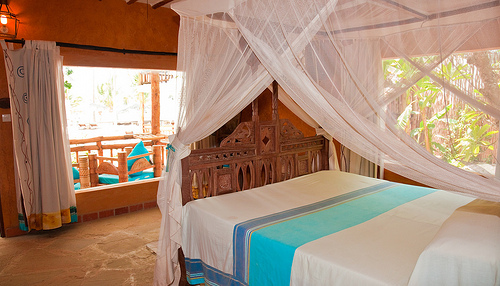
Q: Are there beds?
A: Yes, there is a bed.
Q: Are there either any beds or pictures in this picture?
A: Yes, there is a bed.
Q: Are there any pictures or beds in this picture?
A: Yes, there is a bed.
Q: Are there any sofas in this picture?
A: No, there are no sofas.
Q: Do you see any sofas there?
A: No, there are no sofas.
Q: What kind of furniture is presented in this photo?
A: The furniture is a bed.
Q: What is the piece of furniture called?
A: The piece of furniture is a bed.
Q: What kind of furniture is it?
A: The piece of furniture is a bed.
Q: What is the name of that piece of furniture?
A: This is a bed.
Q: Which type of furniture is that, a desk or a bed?
A: This is a bed.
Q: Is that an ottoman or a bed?
A: That is a bed.